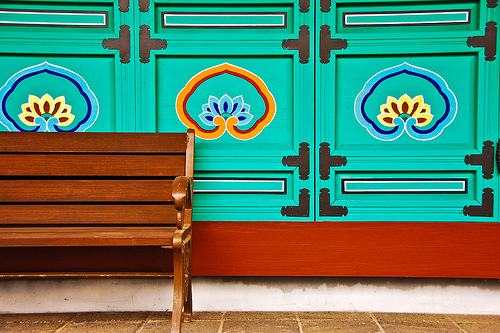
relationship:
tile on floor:
[0, 311, 500, 333] [6, 272, 498, 331]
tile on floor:
[213, 307, 315, 331] [6, 272, 498, 331]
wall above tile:
[0, 2, 500, 313] [218, 297, 478, 331]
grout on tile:
[0, 312, 500, 333] [4, 309, 498, 331]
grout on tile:
[372, 313, 384, 331] [4, 309, 498, 331]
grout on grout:
[0, 312, 500, 333] [0, 312, 500, 333]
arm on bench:
[170, 174, 190, 244] [9, 112, 244, 332]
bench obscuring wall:
[0, 128, 198, 333] [1, 1, 498, 316]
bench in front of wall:
[0, 128, 198, 333] [1, 1, 498, 316]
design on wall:
[173, 61, 276, 141] [0, 2, 499, 279]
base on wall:
[194, 227, 499, 263] [1, 1, 498, 316]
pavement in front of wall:
[0, 308, 498, 330] [1, 1, 498, 316]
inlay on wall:
[281, 24, 348, 63] [196, 0, 498, 277]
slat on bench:
[0, 130, 187, 153] [11, 99, 229, 317]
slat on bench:
[2, 151, 185, 175] [11, 99, 229, 317]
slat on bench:
[1, 175, 176, 202] [11, 99, 229, 317]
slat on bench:
[0, 201, 177, 225] [11, 99, 229, 317]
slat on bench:
[0, 220, 176, 246] [11, 99, 229, 317]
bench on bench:
[0, 128, 198, 333] [0, 128, 198, 333]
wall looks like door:
[0, 2, 499, 279] [4, 5, 136, 132]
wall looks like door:
[0, 2, 499, 279] [137, 2, 312, 219]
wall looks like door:
[0, 2, 499, 279] [317, 0, 497, 221]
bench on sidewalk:
[10, 125, 222, 322] [2, 311, 484, 331]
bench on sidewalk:
[0, 128, 198, 333] [1, 281, 481, 331]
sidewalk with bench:
[0, 312, 500, 333] [0, 128, 198, 333]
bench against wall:
[0, 128, 198, 333] [0, 2, 499, 279]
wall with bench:
[0, 2, 499, 279] [0, 128, 198, 333]